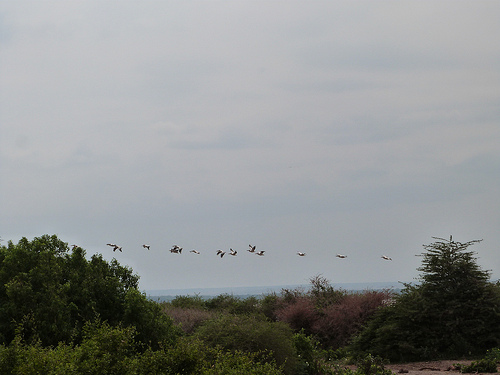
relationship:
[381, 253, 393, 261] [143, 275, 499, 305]
bird over sea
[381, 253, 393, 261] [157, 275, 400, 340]
bird over shrubs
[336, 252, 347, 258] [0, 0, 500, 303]
bird in sky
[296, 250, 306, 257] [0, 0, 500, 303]
bird in sky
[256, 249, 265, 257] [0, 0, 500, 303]
bird in sky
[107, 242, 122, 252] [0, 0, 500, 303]
bird in sky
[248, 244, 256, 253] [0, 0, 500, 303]
bird in sky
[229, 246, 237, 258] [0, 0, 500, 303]
bird in sky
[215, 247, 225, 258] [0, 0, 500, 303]
bird in sky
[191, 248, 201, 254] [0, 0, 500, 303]
bird in sky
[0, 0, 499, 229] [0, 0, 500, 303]
clouds in sky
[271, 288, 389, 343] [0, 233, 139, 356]
bushes near tree